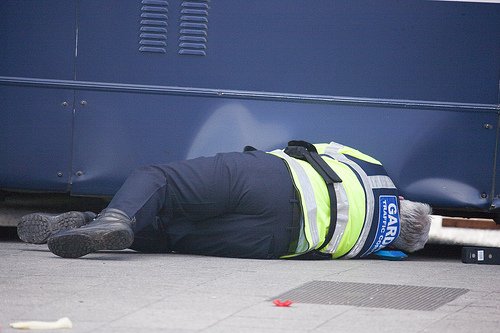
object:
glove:
[10, 317, 71, 330]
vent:
[269, 279, 473, 312]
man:
[15, 140, 430, 260]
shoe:
[15, 211, 132, 259]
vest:
[265, 142, 400, 260]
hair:
[390, 200, 431, 253]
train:
[1, 0, 500, 218]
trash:
[273, 300, 292, 307]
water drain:
[264, 278, 471, 312]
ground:
[0, 260, 499, 333]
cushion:
[371, 250, 408, 261]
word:
[361, 196, 401, 259]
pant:
[93, 146, 291, 259]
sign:
[358, 196, 400, 258]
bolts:
[62, 102, 68, 106]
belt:
[288, 188, 301, 256]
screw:
[82, 101, 86, 105]